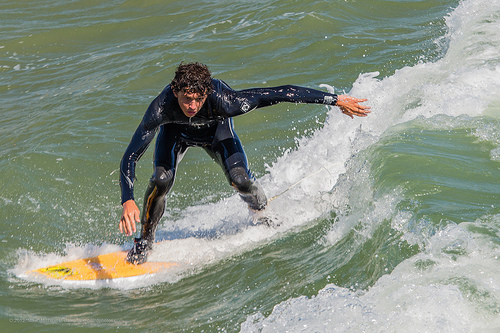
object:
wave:
[400, 40, 496, 120]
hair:
[171, 58, 214, 97]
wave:
[309, 187, 408, 227]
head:
[172, 60, 213, 119]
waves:
[1, 12, 92, 47]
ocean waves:
[415, 217, 471, 266]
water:
[389, 0, 471, 26]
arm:
[117, 103, 160, 204]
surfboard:
[33, 219, 267, 290]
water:
[3, 302, 53, 327]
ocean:
[0, 0, 498, 332]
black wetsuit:
[117, 77, 338, 205]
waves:
[431, 2, 488, 45]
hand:
[336, 94, 373, 121]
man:
[116, 59, 373, 267]